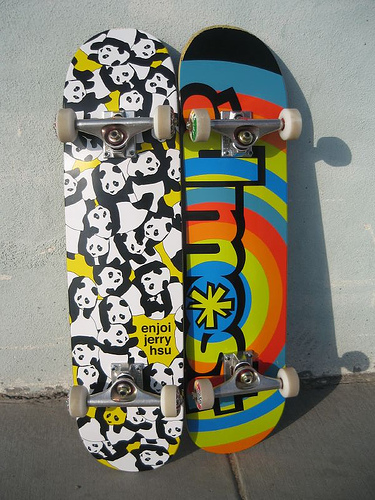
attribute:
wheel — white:
[158, 381, 177, 424]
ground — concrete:
[13, 391, 349, 498]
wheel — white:
[278, 107, 305, 144]